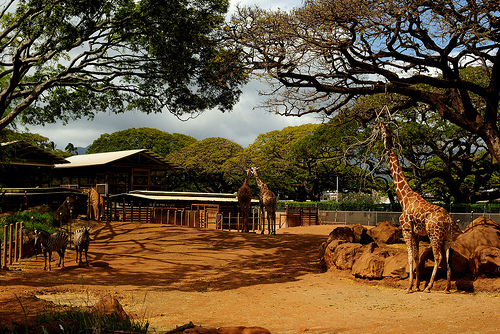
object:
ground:
[0, 224, 500, 334]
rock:
[332, 241, 363, 271]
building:
[52, 147, 189, 222]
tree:
[166, 136, 247, 193]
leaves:
[268, 133, 271, 135]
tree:
[218, 0, 500, 173]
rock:
[351, 251, 386, 279]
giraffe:
[378, 121, 455, 295]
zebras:
[71, 225, 92, 268]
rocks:
[468, 245, 500, 280]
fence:
[0, 220, 24, 266]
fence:
[86, 190, 288, 233]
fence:
[316, 209, 500, 231]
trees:
[0, 0, 251, 136]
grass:
[0, 208, 57, 244]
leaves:
[222, 109, 226, 113]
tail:
[448, 220, 455, 267]